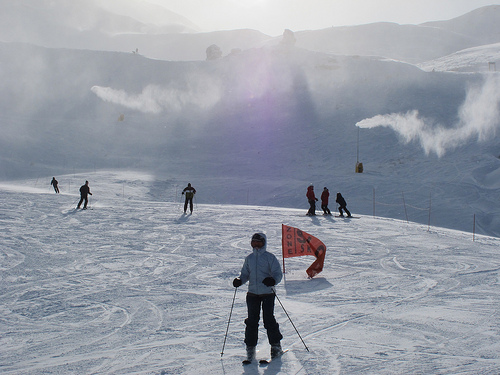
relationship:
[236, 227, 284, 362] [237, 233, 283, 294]
person wearing jacket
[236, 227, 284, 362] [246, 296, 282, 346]
person wearing pants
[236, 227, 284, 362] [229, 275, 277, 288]
person wearing gloves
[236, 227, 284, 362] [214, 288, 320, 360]
person holding poles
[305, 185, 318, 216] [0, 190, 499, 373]
skier on ski slope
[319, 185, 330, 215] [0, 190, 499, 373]
skier on ski slope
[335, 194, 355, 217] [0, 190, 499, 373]
skier on ski slope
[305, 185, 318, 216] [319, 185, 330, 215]
skier next to skier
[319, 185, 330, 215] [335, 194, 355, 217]
skier next to skier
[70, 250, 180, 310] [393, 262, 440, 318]
ski tracks on snow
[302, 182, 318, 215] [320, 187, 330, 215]
skier next to skier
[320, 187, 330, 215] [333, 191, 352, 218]
skier next to skier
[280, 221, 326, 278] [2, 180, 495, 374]
flag planted in snow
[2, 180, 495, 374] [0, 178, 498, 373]
snow on hill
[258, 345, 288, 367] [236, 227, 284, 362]
ski on person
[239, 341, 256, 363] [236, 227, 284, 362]
ski on person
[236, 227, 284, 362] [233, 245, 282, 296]
person wears parka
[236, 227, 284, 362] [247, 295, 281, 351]
person wears pants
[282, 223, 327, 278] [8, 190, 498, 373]
flag on slope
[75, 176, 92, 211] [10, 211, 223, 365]
skier skiing on slope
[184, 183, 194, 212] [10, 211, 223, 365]
skier skiing on slope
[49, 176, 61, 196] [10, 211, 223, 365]
skier skiing on slope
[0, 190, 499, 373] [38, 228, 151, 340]
ski slope with ski tracks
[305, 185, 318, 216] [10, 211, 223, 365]
skier are skiing on slope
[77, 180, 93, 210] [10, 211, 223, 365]
skier skiing on slope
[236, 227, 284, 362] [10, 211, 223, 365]
person skiing on slope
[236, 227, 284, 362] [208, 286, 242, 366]
person holding ski poles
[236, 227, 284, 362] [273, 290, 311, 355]
person holding ski poles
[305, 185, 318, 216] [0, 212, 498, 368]
skier resting on run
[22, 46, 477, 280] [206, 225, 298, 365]
ski resort in cake